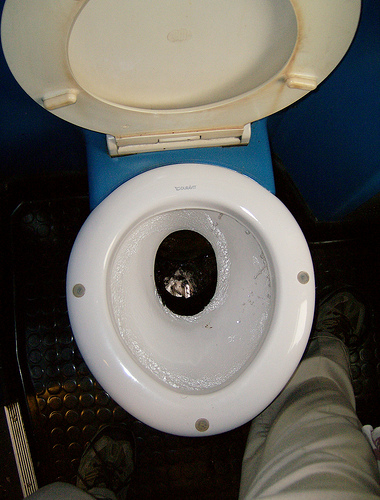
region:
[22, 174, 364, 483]
a man stands over a toilet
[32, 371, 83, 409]
raised pattern on the floor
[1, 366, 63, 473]
metal floor of the bathroom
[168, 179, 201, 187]
manufacturer's brand name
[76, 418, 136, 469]
tip of a running shoe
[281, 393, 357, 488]
khaki pants leg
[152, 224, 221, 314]
black hole in a toilet bowl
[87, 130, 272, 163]
hinged base of the toilet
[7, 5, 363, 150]
set in the up position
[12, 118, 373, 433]
bathroom with cramped quarters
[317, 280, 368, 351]
The brown boot of the man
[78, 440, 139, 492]
The black laces of the brown shoe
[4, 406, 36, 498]
the metal rail in the doorway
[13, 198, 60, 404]
Bumps on the floor of the bathroom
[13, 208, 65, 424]
the floor of the bathroom is black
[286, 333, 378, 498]
The tan leg of the mans pant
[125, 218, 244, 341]
Water draining into the hole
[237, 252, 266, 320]
water falling into the bowl of the toilet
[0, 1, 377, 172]
the whit toilet seat sitting up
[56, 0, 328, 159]
The white toilet seat stained with dirt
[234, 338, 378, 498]
a person's leg in the bathroom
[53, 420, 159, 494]
a person's shoe in the bathroom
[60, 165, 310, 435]
a toilet seat in a bathroom stall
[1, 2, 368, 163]
a toilet lid in a bathroom stall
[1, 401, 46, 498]
a door hinge in a bathroom stall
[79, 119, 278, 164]
a toilet lid hinge in a bathroom stall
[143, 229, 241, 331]
inside of a toilet in a bathroom stall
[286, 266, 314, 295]
spot on a toilet seat in a bathroom stall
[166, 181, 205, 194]
writing on a toilet seat in a bathroom stall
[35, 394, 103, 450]
metal bubbles in the floor of a bathroom stall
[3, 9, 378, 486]
a toilet in a bathroom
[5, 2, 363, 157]
lid of toilet is up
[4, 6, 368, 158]
lid of toilet is old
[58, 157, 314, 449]
toilet is color white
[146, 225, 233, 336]
base of toilet is color black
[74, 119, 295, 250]
support of toilet is blue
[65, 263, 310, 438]
three gray dots on toilet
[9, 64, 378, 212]
wall of bathroom is blue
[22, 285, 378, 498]
two legs on front a toilet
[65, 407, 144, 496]
a black shoe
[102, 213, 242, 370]
This is a toilet bowl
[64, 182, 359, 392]
This is a portable toilet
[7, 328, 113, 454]
This is a black mat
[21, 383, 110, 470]
The black mat is textured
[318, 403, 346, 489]
This is a man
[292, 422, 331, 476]
The pants are taupe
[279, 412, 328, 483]
The pants are khaki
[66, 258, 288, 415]
The toilet is white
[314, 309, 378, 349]
These are shoes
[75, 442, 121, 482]
The shoes are black